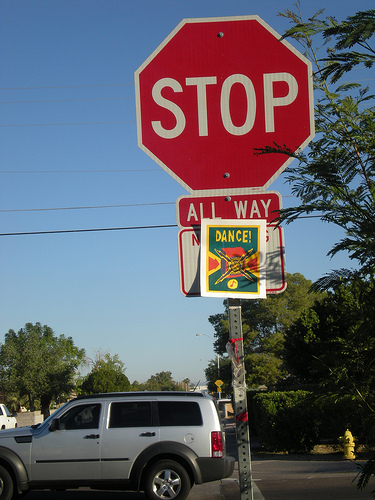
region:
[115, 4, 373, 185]
stop sign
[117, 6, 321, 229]
red eight sided stop sign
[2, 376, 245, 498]
grey car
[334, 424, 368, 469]
yellow fire hydrant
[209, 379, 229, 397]
yellow traffic sign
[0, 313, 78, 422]
green big tree on the side of the street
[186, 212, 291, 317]
event flyer with the word dance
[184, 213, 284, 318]
event flyer taped to stop sign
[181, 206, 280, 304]
event flyer covering traffic sign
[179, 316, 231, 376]
two white light post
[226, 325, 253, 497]
Gray post holding up sign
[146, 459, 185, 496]
Rear tire of the car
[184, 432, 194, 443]
Gas tank door on the car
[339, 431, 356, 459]
Yellow hydrant near the road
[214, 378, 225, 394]
Yellow sign to the right of the car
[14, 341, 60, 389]
Green tree to the left of the car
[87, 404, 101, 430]
Driver in the car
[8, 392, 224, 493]
Silver car on the road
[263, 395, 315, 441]
Green shrubbery next to a hydrant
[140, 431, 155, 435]
Door handle on the car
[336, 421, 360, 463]
a yellow fire hydrant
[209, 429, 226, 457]
taillights of a car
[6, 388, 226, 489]
a silver car crossing a street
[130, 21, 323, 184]
a stop sign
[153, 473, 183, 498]
a silvery hubcap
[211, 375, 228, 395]
yellow signs on a pole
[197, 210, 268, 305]
a printed sheet of paper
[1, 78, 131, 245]
a bunch of wires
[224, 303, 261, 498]
a metal pole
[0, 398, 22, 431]
a parked white car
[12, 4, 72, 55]
the clear blue sky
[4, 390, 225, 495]
the suv in the street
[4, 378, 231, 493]
the suv is silver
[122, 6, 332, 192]
the stop sign on the pole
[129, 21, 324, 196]
the stop sign is red and white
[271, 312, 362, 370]
the trees with green leaves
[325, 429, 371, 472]
the hydrant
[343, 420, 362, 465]
the hydrant is yellow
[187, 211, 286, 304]
paper below the stop sign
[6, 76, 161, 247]
power lines above the suv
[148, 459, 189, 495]
a wheel of a vehicle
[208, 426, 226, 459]
the tail light of a vehicle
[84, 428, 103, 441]
door handle on a vehicle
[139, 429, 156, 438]
door handle on a vehicle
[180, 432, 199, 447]
gas tank door of a vehicle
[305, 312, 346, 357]
the leaves of trees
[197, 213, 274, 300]
a sign advertising "dance"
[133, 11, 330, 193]
a red and white stop sign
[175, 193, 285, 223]
a red and white "all way" sign